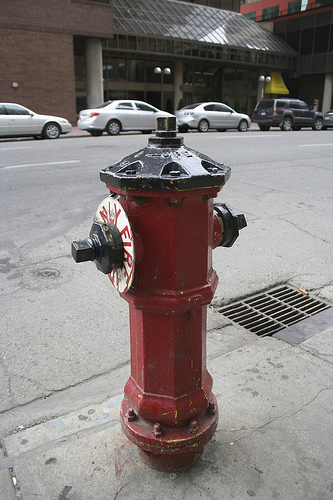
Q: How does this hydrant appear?
A: Red in color.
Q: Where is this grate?
A: Side of street.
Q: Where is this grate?
A: Near curb.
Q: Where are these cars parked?
A: On other side of street.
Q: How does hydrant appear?
A: Red in color.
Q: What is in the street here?
A: Storm drain.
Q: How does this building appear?
A: Brick.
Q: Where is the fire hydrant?
A: On the sidewalk.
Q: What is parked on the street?
A: Cars.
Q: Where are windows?
A: On the cars.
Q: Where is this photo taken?
A: Street.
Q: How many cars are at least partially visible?
A: Five.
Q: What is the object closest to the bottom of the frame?
A: Hydrant.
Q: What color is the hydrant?
A: Red.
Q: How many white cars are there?
A: Three.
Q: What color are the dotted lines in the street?
A: White.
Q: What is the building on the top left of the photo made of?
A: Bricks.